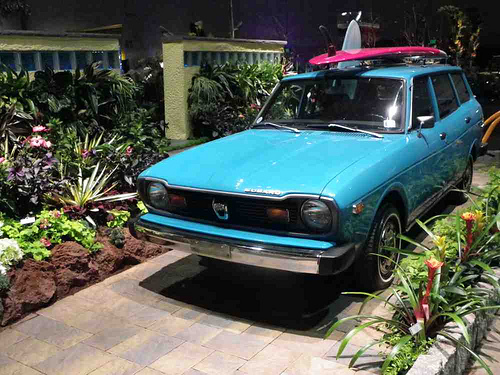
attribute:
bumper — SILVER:
[133, 197, 350, 281]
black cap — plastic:
[323, 239, 355, 279]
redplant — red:
[413, 259, 443, 327]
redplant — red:
[459, 204, 476, 259]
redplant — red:
[27, 131, 45, 154]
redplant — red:
[26, 123, 48, 133]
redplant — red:
[36, 236, 50, 246]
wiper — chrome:
[333, 122, 388, 143]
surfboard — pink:
[307, 24, 447, 65]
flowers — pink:
[19, 120, 56, 158]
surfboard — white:
[307, 17, 451, 65]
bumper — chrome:
[132, 213, 327, 280]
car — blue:
[123, 44, 484, 259]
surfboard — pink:
[339, 42, 414, 69]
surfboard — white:
[331, 18, 361, 98]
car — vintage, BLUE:
[128, 47, 495, 310]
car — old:
[124, 43, 486, 293]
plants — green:
[192, 65, 258, 125]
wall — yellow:
[155, 42, 290, 110]